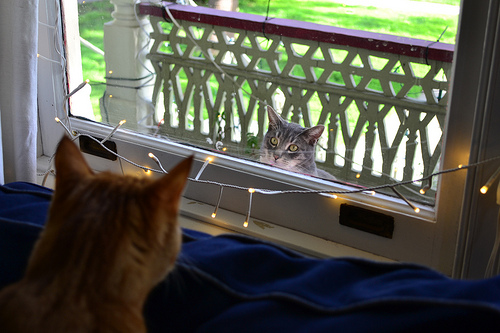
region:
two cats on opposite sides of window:
[25, 47, 410, 298]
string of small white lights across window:
[37, 41, 478, 231]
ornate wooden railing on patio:
[142, 5, 437, 175]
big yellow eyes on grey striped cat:
[240, 70, 335, 185]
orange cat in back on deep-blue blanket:
[21, 125, 241, 325]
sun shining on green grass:
[151, 6, 468, 56]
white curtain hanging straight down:
[10, 5, 50, 185]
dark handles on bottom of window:
[71, 130, 402, 245]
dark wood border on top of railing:
[150, 5, 452, 67]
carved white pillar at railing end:
[95, 2, 165, 132]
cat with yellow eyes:
[252, 101, 334, 183]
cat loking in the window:
[245, 82, 339, 200]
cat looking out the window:
[22, 128, 216, 309]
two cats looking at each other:
[27, 65, 361, 300]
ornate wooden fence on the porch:
[151, 5, 445, 113]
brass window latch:
[318, 184, 415, 245]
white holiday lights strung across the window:
[200, 157, 487, 214]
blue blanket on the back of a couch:
[210, 231, 401, 313]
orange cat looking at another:
[5, 134, 220, 301]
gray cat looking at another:
[262, 100, 333, 178]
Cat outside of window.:
[251, 97, 338, 187]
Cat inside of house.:
[1, 128, 216, 330]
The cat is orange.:
[0, 136, 203, 331]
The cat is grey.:
[259, 100, 328, 180]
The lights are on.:
[40, 103, 498, 243]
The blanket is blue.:
[0, 173, 497, 329]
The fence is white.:
[95, 1, 459, 210]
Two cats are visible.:
[2, 100, 329, 328]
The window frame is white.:
[28, 2, 498, 285]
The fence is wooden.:
[99, 2, 449, 218]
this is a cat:
[250, 116, 323, 171]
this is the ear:
[302, 122, 327, 139]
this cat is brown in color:
[0, 153, 191, 331]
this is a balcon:
[364, 62, 425, 122]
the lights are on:
[205, 180, 271, 225]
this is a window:
[285, 5, 421, 110]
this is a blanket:
[266, 256, 396, 311]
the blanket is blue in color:
[278, 266, 408, 327]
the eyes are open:
[266, 135, 296, 151]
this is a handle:
[348, 213, 385, 223]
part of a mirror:
[308, 95, 340, 135]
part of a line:
[250, 283, 279, 302]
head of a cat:
[83, 179, 124, 239]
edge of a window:
[439, 90, 464, 140]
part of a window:
[243, 111, 296, 183]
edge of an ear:
[169, 129, 196, 175]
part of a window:
[115, 116, 160, 146]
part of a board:
[301, 199, 371, 242]